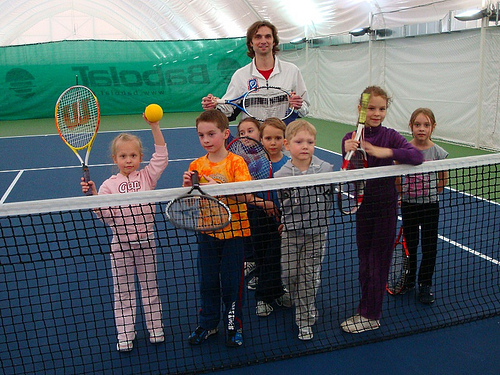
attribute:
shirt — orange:
[224, 156, 244, 173]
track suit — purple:
[343, 114, 416, 213]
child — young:
[45, 89, 454, 352]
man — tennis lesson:
[204, 20, 314, 141]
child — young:
[83, 100, 189, 350]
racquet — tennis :
[43, 77, 108, 207]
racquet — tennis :
[50, 75, 115, 225]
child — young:
[68, 100, 194, 351]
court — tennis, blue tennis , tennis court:
[3, 114, 484, 354]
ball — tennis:
[136, 100, 164, 124]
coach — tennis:
[199, 20, 308, 142]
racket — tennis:
[48, 75, 108, 218]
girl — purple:
[343, 85, 419, 329]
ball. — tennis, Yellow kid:
[131, 99, 177, 129]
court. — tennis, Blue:
[9, 136, 484, 359]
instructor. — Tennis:
[166, 21, 331, 200]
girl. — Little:
[56, 84, 166, 345]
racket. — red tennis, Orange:
[165, 177, 243, 245]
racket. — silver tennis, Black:
[163, 181, 243, 248]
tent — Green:
[4, 38, 277, 125]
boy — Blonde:
[279, 108, 332, 331]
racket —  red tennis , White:
[51, 80, 118, 197]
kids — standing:
[56, 69, 451, 343]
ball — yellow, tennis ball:
[145, 105, 161, 118]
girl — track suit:
[58, 82, 168, 345]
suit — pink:
[91, 151, 165, 344]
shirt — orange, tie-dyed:
[181, 154, 256, 237]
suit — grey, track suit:
[275, 164, 338, 314]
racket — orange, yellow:
[56, 87, 99, 177]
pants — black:
[401, 201, 440, 294]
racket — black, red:
[389, 229, 409, 290]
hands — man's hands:
[202, 87, 301, 105]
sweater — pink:
[96, 149, 170, 234]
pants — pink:
[107, 232, 166, 343]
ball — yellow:
[143, 105, 161, 121]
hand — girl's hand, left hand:
[143, 111, 164, 126]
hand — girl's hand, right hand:
[78, 179, 91, 194]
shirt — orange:
[180, 160, 253, 232]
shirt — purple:
[343, 131, 415, 198]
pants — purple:
[354, 193, 394, 314]